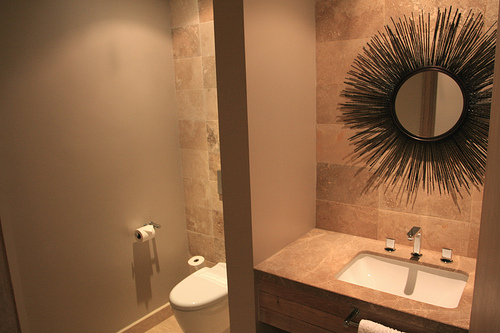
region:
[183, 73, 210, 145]
tile wall for style and design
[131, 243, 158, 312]
shadow of toilet paper roll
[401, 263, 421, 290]
shadow of faucet ink sink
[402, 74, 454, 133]
mirror to show one's reflection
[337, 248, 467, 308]
sink bowl for holding water in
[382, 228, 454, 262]
knobs and faucet for water control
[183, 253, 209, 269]
spare toilet paper roll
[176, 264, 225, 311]
toilet lid for closing toilet hole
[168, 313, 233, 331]
toilet bowl for holding human waste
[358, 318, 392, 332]
white towel for drying hands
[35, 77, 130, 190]
The bathroom wall is biege.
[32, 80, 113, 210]
The bathroom wall is smooth.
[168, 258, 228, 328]
The toilet is white.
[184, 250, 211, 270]
The toilet paper is white.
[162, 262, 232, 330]
The toilet lid is closed.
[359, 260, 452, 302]
The bathroom sink is white.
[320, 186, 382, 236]
The bathroom tile is biege.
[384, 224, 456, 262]
The bathroom fixtures are silver.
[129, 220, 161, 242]
The toilet paper is on the wall.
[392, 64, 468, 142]
The mirror is shaped in a circle.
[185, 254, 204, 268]
spare roll of toilet paper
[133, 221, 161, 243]
toilet paper on chrome holder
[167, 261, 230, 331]
white porcelain tankless toilet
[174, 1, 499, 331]
marble bathroom counter and wall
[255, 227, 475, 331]
single sink mounted in marble cabinet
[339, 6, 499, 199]
round batghroom mirror with elaborate metalwork frame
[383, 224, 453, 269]
modern style chrome faucet handles and spout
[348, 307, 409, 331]
towel rack on front of sink cabinet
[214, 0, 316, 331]
support wall for bathroom sink cabinet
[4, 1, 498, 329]
luxurious styled minimalist bathroom with marble wall and counter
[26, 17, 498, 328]
this is a bathroom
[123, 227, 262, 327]
this is a toilet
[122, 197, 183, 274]
toilet paper on the wall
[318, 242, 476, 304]
this is a sink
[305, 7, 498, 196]
this is a mirror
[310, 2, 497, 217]
mirror is on the wall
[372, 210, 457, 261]
this is a faucet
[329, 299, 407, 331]
towel rack on counter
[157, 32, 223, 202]
tile on the wall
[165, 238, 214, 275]
extra roll of toilet paper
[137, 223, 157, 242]
a roll of toilet paper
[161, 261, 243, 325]
the toilet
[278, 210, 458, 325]
the counter in the bathroom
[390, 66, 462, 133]
a mirror on the wall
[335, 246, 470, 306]
the faucet on the sink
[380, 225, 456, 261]
the faucet on the sink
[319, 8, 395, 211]
tiles on the wall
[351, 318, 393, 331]
a towel hanging from the sink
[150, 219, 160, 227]
a hook on the wall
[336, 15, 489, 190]
a mirror wreath on the wall